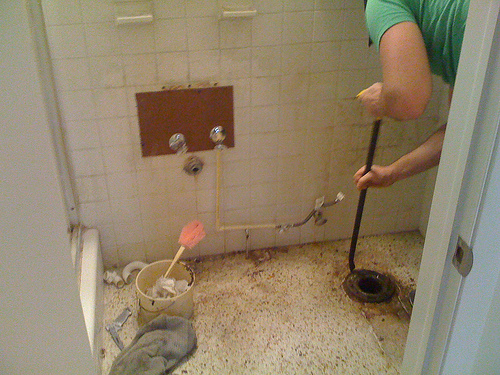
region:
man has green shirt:
[344, 3, 484, 75]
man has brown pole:
[343, 82, 421, 269]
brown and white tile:
[237, 267, 327, 357]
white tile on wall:
[260, 65, 342, 186]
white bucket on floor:
[137, 264, 201, 324]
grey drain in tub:
[343, 244, 375, 294]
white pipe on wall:
[187, 151, 299, 231]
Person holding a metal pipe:
[344, 0, 470, 270]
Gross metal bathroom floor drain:
[342, 264, 396, 306]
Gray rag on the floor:
[107, 311, 199, 373]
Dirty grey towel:
[103, 311, 198, 373]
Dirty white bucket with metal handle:
[135, 257, 197, 324]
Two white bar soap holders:
[112, 4, 262, 25]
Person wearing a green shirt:
[355, 0, 475, 192]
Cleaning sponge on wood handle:
[161, 218, 206, 283]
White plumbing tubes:
[100, 255, 150, 290]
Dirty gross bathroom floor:
[96, 227, 425, 372]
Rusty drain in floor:
[346, 265, 402, 301]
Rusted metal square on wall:
[125, 77, 240, 152]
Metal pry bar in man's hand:
[341, 105, 372, 266]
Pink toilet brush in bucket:
[165, 221, 206, 276]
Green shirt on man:
[360, 2, 460, 79]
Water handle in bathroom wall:
[311, 200, 326, 226]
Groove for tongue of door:
[447, 235, 467, 270]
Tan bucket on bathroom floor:
[135, 256, 196, 321]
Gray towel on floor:
[101, 310, 201, 372]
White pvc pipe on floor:
[101, 255, 151, 290]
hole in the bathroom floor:
[347, 265, 399, 300]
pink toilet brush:
[174, 217, 211, 249]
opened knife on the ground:
[104, 300, 141, 357]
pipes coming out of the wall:
[165, 127, 348, 237]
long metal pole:
[342, 105, 387, 280]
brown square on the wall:
[131, 76, 246, 163]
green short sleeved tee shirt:
[361, 0, 477, 82]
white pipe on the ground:
[103, 255, 150, 297]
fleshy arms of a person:
[351, 29, 442, 192]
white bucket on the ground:
[129, 255, 202, 327]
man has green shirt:
[353, 10, 474, 93]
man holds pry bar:
[328, 106, 395, 279]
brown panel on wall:
[131, 81, 241, 171]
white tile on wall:
[230, 41, 301, 146]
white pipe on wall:
[183, 156, 281, 241]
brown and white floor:
[226, 265, 283, 374]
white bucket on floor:
[113, 240, 191, 327]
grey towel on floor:
[116, 326, 176, 369]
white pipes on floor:
[106, 249, 154, 279]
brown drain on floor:
[328, 262, 415, 325]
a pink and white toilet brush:
[157, 220, 216, 281]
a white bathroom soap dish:
[114, 1, 156, 21]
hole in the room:
[288, 228, 438, 323]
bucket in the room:
[114, 239, 221, 330]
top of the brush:
[161, 208, 222, 254]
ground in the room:
[213, 269, 305, 344]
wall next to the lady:
[261, 55, 333, 127]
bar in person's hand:
[304, 105, 417, 282]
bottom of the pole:
[301, 238, 378, 295]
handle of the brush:
[147, 250, 194, 285]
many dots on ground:
[208, 272, 327, 362]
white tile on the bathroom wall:
[90, 83, 129, 121]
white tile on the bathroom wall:
[95, 113, 133, 149]